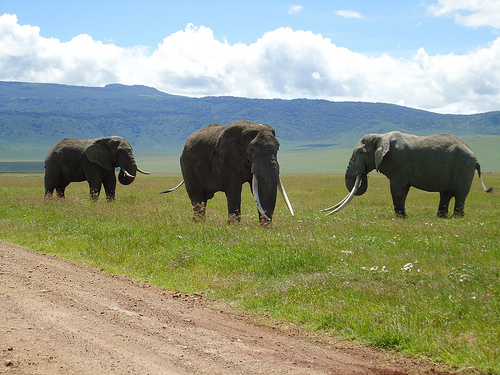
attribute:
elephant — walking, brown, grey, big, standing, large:
[43, 133, 151, 202]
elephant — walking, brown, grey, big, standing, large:
[160, 118, 296, 226]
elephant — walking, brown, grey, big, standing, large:
[319, 131, 494, 221]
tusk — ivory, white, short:
[121, 168, 136, 180]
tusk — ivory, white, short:
[136, 168, 150, 176]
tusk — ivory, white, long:
[250, 174, 272, 222]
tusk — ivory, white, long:
[276, 173, 295, 218]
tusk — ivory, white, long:
[323, 175, 361, 216]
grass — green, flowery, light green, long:
[0, 172, 499, 374]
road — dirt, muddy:
[0, 239, 438, 374]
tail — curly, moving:
[158, 174, 186, 194]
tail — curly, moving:
[474, 162, 495, 194]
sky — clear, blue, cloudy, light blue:
[1, 1, 499, 115]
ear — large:
[81, 141, 117, 173]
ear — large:
[210, 124, 247, 189]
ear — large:
[374, 133, 390, 175]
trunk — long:
[117, 154, 137, 186]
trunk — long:
[250, 157, 282, 225]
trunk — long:
[345, 151, 369, 198]